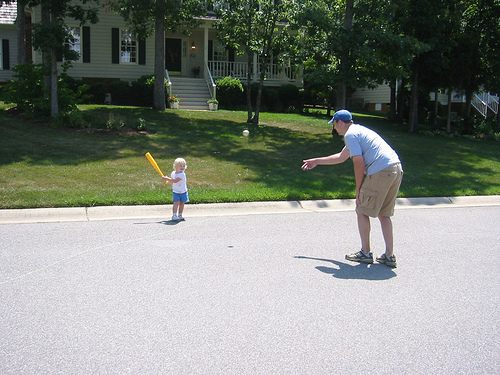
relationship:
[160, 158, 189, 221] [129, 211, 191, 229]
girl has shadow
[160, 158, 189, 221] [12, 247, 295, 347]
girl plays in street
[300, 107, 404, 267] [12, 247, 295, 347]
man plays in street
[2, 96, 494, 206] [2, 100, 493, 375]
grass on ground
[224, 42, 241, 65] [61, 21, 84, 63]
shutter on window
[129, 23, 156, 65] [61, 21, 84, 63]
shutter on window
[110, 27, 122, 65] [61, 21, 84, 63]
shutter on window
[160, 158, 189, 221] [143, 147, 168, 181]
girl has bat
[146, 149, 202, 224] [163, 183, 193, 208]
girl has shorts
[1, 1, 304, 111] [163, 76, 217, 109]
house has steps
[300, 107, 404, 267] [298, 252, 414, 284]
man has shadow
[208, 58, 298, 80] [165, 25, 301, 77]
railing around porch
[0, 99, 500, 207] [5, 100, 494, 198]
grass in yard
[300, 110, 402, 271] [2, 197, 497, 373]
man in street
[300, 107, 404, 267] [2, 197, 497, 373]
man standing on street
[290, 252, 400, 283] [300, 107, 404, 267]
shadow of man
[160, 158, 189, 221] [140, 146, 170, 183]
girl holding bat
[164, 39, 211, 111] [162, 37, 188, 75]
steps leading to door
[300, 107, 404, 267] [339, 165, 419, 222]
man wears shorts